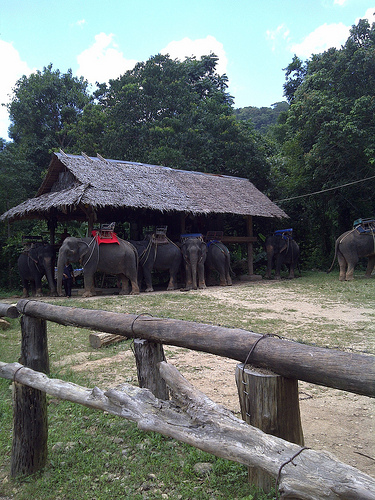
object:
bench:
[205, 231, 223, 241]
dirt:
[213, 288, 217, 296]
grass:
[178, 309, 189, 318]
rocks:
[113, 435, 122, 443]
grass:
[0, 484, 10, 497]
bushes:
[336, 56, 338, 60]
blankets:
[206, 240, 220, 248]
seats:
[354, 216, 375, 235]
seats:
[274, 228, 292, 240]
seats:
[22, 236, 43, 253]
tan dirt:
[277, 289, 281, 295]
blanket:
[91, 230, 119, 245]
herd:
[18, 227, 235, 302]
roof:
[55, 152, 290, 220]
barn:
[0, 149, 294, 296]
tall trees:
[0, 145, 42, 270]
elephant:
[176, 236, 208, 291]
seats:
[179, 233, 203, 242]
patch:
[176, 299, 189, 317]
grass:
[0, 337, 12, 354]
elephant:
[18, 244, 55, 299]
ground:
[310, 313, 333, 349]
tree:
[61, 52, 269, 190]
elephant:
[327, 223, 375, 281]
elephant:
[205, 240, 236, 286]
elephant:
[266, 235, 299, 279]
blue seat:
[180, 233, 202, 237]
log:
[5, 357, 374, 498]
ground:
[228, 289, 254, 310]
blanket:
[355, 225, 375, 233]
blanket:
[275, 233, 293, 240]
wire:
[242, 333, 265, 368]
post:
[233, 362, 307, 500]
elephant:
[130, 237, 181, 292]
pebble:
[154, 489, 162, 494]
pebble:
[122, 454, 128, 460]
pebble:
[160, 493, 168, 499]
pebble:
[149, 473, 155, 478]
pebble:
[141, 481, 147, 489]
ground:
[342, 409, 367, 457]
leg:
[129, 263, 140, 295]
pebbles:
[51, 440, 62, 450]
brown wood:
[16, 298, 126, 337]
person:
[63, 259, 74, 297]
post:
[10, 302, 49, 473]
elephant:
[57, 233, 140, 298]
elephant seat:
[142, 224, 169, 244]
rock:
[193, 462, 212, 472]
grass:
[72, 479, 89, 500]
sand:
[334, 312, 339, 319]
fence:
[0, 296, 374, 495]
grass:
[367, 279, 371, 295]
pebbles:
[211, 368, 215, 370]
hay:
[169, 176, 184, 196]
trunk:
[56, 247, 67, 293]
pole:
[162, 313, 319, 374]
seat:
[98, 221, 115, 239]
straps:
[154, 244, 158, 262]